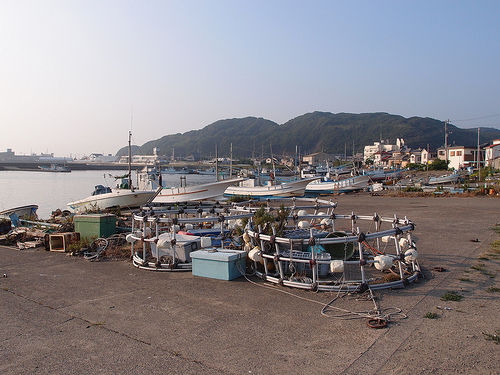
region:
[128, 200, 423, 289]
large crab rings on the ground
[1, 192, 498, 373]
a paved marina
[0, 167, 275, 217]
a calm body of water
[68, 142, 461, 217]
a row of ships at the marina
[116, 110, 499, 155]
a tree-covered hillside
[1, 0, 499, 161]
blue sky above the water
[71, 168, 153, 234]
A BOAT OUT OF WATER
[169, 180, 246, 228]
A BOAT OUT OF WATER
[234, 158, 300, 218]
A BOAT OUT OF WATER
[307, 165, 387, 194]
A BOAT OUT OF WATER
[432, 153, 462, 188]
A BOAT OUT OF WATER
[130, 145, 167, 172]
A BOAT OUT OF WATER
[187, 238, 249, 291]
a box on the ground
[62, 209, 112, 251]
a box on the ground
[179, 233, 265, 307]
a blue box on ground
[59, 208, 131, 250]
a green box on ground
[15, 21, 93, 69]
white clouds in blue sky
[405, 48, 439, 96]
white clouds in blue sky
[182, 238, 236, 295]
blue container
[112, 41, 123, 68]
white clouds in blue sky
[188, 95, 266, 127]
white clouds in blue sky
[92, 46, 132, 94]
white clouds in blue sky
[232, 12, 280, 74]
white clouds in blue sky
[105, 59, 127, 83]
white clouds in blue sky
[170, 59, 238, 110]
white clouds in blue sky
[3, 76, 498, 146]
The sky is clear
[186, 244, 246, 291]
The light blue box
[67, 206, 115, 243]
The olive green box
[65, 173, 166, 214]
The boat that is leaning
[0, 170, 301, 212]
The water is calm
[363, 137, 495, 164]
The buildings in the background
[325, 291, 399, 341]
The rope on the ground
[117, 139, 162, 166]
The cruise ship in the back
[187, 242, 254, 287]
a blue box with a rope attached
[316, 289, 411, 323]
ropes laying on the ground